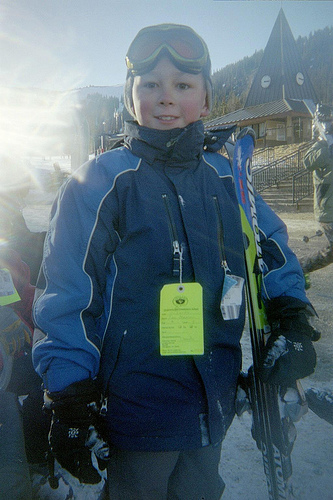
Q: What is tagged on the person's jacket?
A: A yellow tag.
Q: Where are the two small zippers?
A: On the front side of the jacket.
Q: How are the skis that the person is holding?
A: Blue and green.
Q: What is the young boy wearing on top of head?
A: Ski goggles.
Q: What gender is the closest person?
A: Male.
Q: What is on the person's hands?
A: Gloves.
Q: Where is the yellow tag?
A: On the person's coat.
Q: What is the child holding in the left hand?
A: Skis.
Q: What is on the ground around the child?
A: Snow.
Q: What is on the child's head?
A: Goggles.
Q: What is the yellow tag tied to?
A: Zipper.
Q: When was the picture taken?
A: During the day.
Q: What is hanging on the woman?
A: A tag.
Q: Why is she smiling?
A: She is happy.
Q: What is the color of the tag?
A: Yellow.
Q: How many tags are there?
A: 2.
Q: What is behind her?
A: A house.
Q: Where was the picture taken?
A: In Switzerland.